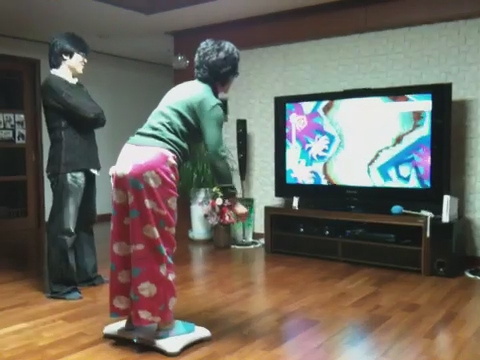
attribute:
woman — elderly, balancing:
[111, 37, 250, 336]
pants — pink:
[108, 144, 181, 326]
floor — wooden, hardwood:
[176, 242, 478, 360]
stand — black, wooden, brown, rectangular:
[265, 204, 432, 275]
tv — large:
[274, 81, 453, 213]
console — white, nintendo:
[442, 192, 459, 224]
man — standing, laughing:
[40, 30, 104, 299]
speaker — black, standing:
[236, 119, 247, 182]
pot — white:
[187, 189, 215, 239]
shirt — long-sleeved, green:
[129, 77, 238, 199]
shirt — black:
[40, 75, 107, 170]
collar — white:
[51, 67, 79, 85]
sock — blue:
[158, 320, 194, 339]